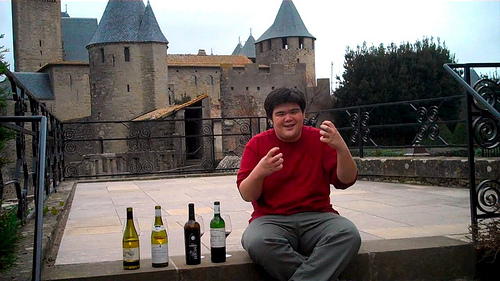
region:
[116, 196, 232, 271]
bottles on the wall.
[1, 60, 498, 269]
black wrought iron railing.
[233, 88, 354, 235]
Red shirt on the male.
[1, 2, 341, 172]
Castle in the background.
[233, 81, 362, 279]
Gray pants on the male.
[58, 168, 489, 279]
tiled area outside the building.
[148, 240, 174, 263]
White label on the bottle.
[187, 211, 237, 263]
Wine glasses behind the bottles.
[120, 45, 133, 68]
Open window in the wall.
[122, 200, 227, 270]
four bottles of wine on a step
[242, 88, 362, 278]
young man sitting on a step talking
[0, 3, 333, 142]
a large castle behind the young man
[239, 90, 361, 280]
young man in red t-shirt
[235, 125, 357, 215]
a red shirt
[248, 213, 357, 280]
the man's gray pants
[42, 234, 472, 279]
top step to a stone patio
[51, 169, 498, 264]
a stone patio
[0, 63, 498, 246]
black iron railing surrounding the patio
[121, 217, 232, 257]
wine glasses behind the bottles of wine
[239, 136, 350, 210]
man in red shirt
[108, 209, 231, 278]
four bottles on the ledge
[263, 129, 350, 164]
hands are clawed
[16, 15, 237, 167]
castle in the background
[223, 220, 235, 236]
wine glass in back of bottle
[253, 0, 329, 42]
top of roof is blue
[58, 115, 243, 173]
railing surrounds the area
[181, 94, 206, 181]
door way to castle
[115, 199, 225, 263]
four bottles of wine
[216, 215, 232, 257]
a glass with wine in it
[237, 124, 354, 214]
a plain red tee shirt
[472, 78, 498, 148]
decorative metal on the fence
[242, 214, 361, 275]
gray long pants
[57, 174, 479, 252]
stone flooring on the deck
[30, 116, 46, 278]
a black metal hand rail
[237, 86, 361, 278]
the boy is sitting on the step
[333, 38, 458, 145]
a large bush behind the fence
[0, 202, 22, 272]
the bush is green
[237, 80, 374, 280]
thge man sitting on the step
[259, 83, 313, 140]
the smiling face of the man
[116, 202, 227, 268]
the wine bottles on the step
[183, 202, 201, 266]
the drak glass bottle of wine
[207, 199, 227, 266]
the green glass wine bottle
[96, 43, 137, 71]
the windows in the castle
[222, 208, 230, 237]
the side of the glass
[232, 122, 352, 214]
the red tee shirt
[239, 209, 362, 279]
the grey pair of pants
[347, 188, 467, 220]
the lines in the platform behind the man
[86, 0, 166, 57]
roof of a building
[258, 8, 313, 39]
roof of a building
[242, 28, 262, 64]
roof of a building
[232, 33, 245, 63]
roof of a building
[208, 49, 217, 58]
roof of a building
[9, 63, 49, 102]
roof of a building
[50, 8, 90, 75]
roof of a building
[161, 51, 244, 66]
roof of a building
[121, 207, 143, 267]
a bottle for holding liquid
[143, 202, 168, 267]
a bottle for holding liquid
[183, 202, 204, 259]
a bottle for holding liquid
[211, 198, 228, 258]
a bottle for holding liquid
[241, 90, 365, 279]
a person is sitting down